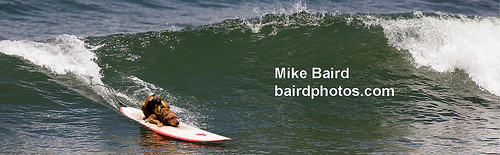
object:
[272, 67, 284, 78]
letter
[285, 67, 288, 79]
letter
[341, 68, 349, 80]
letter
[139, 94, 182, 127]
canine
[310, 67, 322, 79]
letter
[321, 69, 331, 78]
letter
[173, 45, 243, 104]
water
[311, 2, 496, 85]
waves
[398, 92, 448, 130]
ground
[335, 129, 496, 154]
water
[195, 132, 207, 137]
logo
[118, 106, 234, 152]
board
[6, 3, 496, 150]
ocean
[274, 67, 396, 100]
credit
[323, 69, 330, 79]
letter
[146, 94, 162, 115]
clothing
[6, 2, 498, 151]
image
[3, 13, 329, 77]
wave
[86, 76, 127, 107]
cord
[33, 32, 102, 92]
wake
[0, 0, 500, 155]
choppines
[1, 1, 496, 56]
tide